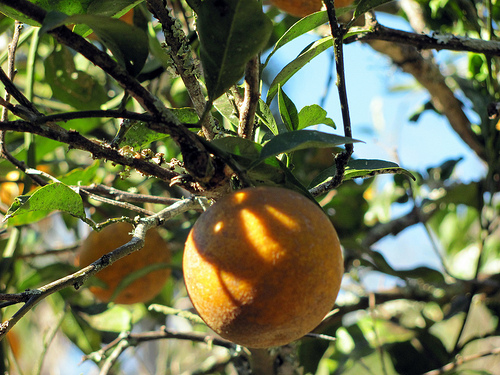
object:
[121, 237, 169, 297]
discoloration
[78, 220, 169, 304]
fruit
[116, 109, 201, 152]
leaf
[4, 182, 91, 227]
leaf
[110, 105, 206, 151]
leaf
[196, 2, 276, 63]
leaf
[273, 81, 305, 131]
leaf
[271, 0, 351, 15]
fruit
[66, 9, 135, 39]
fruit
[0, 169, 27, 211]
fruit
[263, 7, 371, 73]
leaf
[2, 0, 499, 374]
orange tree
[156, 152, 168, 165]
bud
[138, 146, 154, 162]
bud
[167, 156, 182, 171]
bud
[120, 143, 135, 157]
bud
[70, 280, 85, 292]
bud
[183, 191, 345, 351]
fruit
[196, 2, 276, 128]
leaf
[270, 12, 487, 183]
sky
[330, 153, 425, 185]
leaf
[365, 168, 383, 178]
residue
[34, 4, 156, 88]
leaf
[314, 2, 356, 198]
branch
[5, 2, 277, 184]
branches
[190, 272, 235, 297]
sunlight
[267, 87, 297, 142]
leaf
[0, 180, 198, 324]
branch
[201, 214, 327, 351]
tan markings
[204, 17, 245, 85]
scale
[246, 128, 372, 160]
leaf